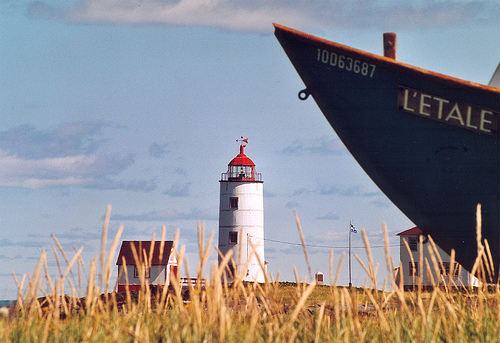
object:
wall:
[373, 122, 429, 179]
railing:
[218, 170, 265, 183]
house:
[393, 226, 482, 293]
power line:
[264, 238, 400, 249]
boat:
[262, 14, 499, 287]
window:
[229, 197, 239, 209]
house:
[112, 238, 182, 298]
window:
[408, 237, 418, 251]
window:
[409, 262, 418, 276]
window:
[439, 262, 459, 275]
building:
[114, 238, 182, 294]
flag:
[350, 223, 358, 234]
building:
[213, 133, 269, 285]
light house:
[216, 134, 268, 286]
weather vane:
[235, 135, 249, 145]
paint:
[397, 84, 495, 138]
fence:
[181, 277, 205, 284]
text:
[399, 86, 495, 135]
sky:
[0, 0, 500, 285]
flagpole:
[349, 220, 353, 289]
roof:
[227, 153, 256, 166]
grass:
[2, 284, 500, 343]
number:
[317, 48, 377, 79]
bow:
[268, 21, 500, 286]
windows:
[230, 197, 238, 208]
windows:
[229, 232, 237, 244]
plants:
[240, 290, 261, 342]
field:
[0, 203, 500, 343]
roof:
[115, 240, 174, 266]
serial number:
[316, 48, 377, 79]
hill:
[197, 282, 401, 307]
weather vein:
[235, 135, 251, 145]